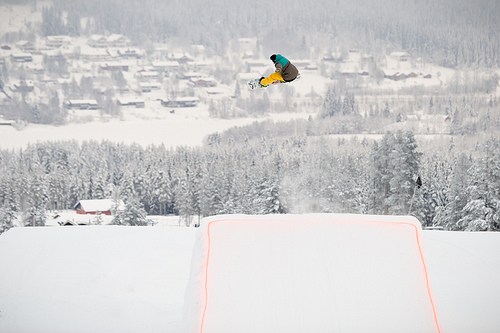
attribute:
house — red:
[82, 199, 162, 236]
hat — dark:
[266, 48, 277, 63]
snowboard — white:
[243, 77, 270, 89]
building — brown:
[74, 196, 126, 216]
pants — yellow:
[255, 73, 292, 88]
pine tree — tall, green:
[389, 135, 419, 216]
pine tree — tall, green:
[368, 121, 393, 211]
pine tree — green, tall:
[355, 140, 383, 205]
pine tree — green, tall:
[326, 141, 358, 215]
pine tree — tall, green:
[281, 152, 361, 229]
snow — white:
[41, 226, 161, 321]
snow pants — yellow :
[253, 65, 283, 87]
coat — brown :
[266, 51, 308, 99]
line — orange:
[406, 221, 447, 331]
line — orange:
[203, 209, 419, 230]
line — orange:
[194, 214, 218, 331]